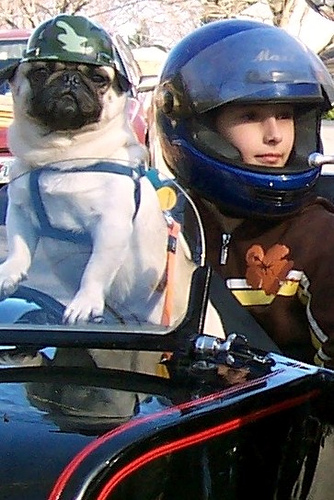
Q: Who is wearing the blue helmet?
A: The woman.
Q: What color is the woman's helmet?
A: Blue.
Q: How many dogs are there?
A: One.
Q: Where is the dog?
A: In front of the woman.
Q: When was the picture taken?
A: Daytime.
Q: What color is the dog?
A: White and black.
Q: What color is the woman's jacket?
A: Brown, yellow, white, and orange.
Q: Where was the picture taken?
A: On the street.